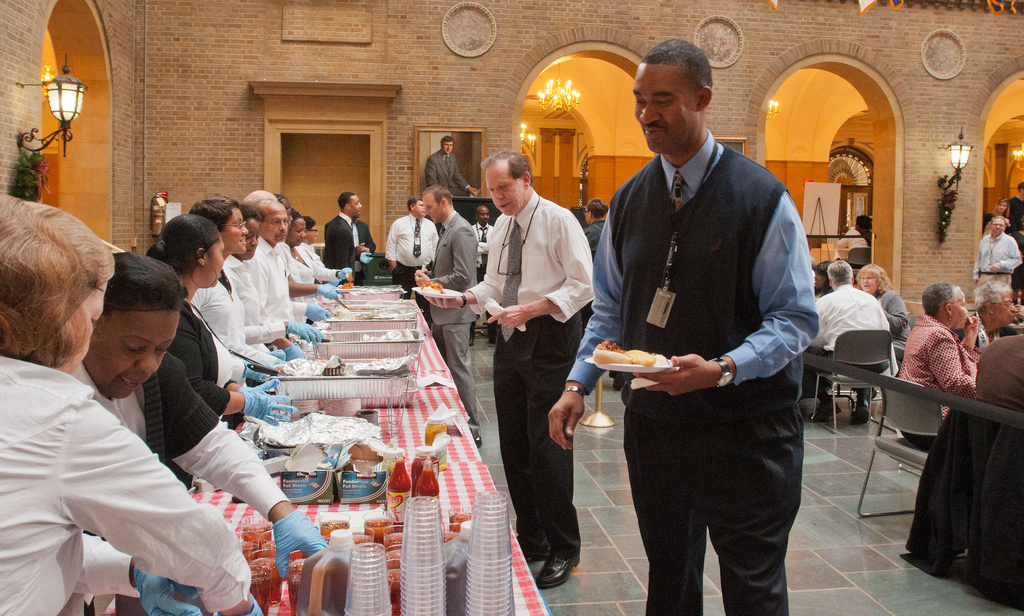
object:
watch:
[710, 357, 734, 387]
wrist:
[706, 355, 738, 388]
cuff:
[725, 343, 760, 386]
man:
[547, 39, 820, 615]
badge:
[646, 287, 676, 328]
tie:
[673, 171, 684, 212]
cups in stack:
[343, 490, 512, 616]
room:
[0, 0, 1024, 616]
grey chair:
[810, 330, 890, 433]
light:
[47, 81, 85, 121]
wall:
[0, 2, 43, 204]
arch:
[38, 0, 114, 246]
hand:
[273, 508, 330, 578]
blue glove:
[273, 510, 330, 579]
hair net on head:
[147, 214, 221, 275]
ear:
[195, 248, 208, 266]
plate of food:
[592, 339, 671, 367]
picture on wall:
[802, 182, 841, 236]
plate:
[584, 355, 680, 373]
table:
[183, 284, 556, 616]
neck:
[663, 129, 710, 169]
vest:
[607, 142, 801, 424]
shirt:
[566, 128, 820, 395]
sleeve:
[725, 192, 821, 386]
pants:
[622, 375, 803, 616]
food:
[592, 339, 671, 367]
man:
[422, 149, 602, 589]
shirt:
[466, 191, 598, 323]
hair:
[480, 150, 534, 187]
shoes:
[536, 549, 582, 590]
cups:
[399, 496, 446, 614]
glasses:
[496, 195, 543, 276]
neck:
[514, 185, 534, 216]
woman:
[147, 213, 298, 427]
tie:
[501, 219, 521, 308]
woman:
[900, 282, 985, 450]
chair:
[857, 373, 944, 518]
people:
[0, 193, 252, 615]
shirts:
[0, 354, 254, 615]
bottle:
[388, 456, 412, 522]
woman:
[63, 253, 328, 579]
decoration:
[440, 1, 498, 58]